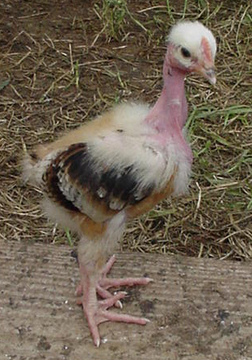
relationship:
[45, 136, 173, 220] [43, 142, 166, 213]
feathers on wing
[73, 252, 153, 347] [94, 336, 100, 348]
claw with nail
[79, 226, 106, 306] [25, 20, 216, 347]
legs of hen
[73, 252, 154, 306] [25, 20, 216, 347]
legs of hen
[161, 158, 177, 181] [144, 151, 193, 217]
part of a chest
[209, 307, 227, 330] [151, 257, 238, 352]
part of a floor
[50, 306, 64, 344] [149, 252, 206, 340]
part of a ground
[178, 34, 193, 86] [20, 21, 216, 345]
eye of a animal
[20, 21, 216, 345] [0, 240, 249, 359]
animal on plank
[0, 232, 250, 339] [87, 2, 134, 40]
plank by grass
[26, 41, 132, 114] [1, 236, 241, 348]
grass near plank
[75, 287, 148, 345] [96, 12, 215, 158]
feet of bird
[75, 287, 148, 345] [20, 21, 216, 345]
feet of animal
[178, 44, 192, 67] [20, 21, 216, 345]
eye of animal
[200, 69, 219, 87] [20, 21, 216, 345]
beak of animal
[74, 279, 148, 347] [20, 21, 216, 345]
claw of animal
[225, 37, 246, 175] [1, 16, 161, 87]
straw on ground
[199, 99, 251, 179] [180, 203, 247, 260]
hay covering ground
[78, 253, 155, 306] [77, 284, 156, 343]
claw of a claw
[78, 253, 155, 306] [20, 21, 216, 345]
claw of a animal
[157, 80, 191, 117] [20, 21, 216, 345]
neck of a animal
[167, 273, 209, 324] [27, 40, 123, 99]
mat on top of grass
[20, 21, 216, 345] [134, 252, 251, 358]
animal standing on mat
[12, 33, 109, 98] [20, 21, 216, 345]
grass near a animal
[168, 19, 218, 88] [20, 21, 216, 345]
face of animal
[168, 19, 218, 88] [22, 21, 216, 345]
face on animal